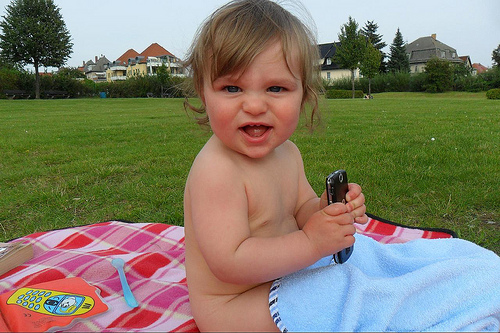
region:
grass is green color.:
[370, 109, 469, 186]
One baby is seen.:
[171, 38, 351, 298]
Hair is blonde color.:
[214, 13, 241, 50]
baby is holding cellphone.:
[321, 161, 365, 286]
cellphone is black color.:
[324, 167, 361, 264]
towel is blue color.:
[369, 257, 441, 314]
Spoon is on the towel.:
[99, 249, 147, 306]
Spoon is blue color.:
[112, 251, 147, 308]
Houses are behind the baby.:
[76, 43, 479, 95]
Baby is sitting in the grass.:
[159, 175, 311, 325]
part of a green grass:
[361, 107, 462, 199]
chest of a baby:
[252, 180, 293, 217]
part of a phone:
[330, 177, 346, 200]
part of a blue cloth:
[358, 280, 406, 326]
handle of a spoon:
[121, 278, 148, 305]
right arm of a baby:
[255, 236, 305, 269]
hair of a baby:
[218, 26, 258, 53]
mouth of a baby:
[245, 120, 268, 142]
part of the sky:
[83, 0, 158, 42]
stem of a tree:
[26, 70, 45, 94]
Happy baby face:
[204, 78, 304, 155]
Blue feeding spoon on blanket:
[94, 241, 143, 311]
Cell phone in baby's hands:
[304, 162, 367, 264]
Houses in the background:
[93, 38, 182, 84]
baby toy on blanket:
[1, 268, 112, 331]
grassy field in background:
[381, 104, 488, 193]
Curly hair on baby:
[159, 54, 211, 131]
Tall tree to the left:
[3, 0, 73, 109]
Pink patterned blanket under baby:
[85, 221, 175, 251]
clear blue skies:
[393, 3, 469, 28]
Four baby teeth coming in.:
[248, 118, 268, 136]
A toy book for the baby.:
[0, 268, 109, 331]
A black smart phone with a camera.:
[316, 168, 366, 266]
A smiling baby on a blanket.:
[117, 3, 439, 326]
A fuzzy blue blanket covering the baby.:
[258, 222, 498, 330]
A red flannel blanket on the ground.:
[3, 194, 468, 329]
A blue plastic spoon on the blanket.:
[103, 252, 141, 318]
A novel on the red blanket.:
[0, 233, 54, 283]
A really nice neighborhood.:
[31, 39, 490, 96]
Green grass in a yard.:
[1, 73, 498, 253]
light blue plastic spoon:
[108, 254, 143, 313]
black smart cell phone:
[322, 166, 360, 272]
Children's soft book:
[0, 274, 107, 328]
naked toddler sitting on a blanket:
[181, 1, 366, 332]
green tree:
[1, 0, 73, 101]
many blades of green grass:
[1, 87, 498, 257]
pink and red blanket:
[1, 217, 468, 329]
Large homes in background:
[30, 42, 189, 81]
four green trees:
[334, 11, 411, 106]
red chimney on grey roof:
[429, 32, 437, 41]